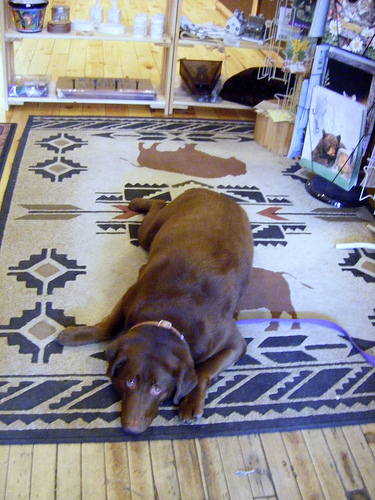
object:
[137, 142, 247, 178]
buffalo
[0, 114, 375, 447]
carpet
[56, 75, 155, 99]
floor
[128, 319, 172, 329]
collar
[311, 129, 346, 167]
bear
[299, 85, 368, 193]
picture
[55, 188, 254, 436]
dog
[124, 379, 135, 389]
eyes